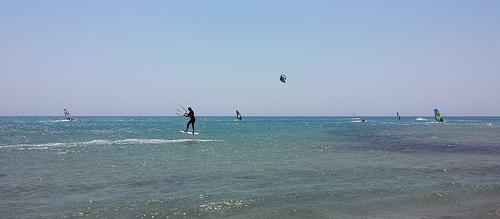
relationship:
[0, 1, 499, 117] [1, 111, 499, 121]
sky has skyline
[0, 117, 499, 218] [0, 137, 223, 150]
water has wave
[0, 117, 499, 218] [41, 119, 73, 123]
water has wave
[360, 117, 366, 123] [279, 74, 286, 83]
person flying kite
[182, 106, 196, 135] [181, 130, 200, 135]
man on top of kiteboard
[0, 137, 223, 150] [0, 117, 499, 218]
wave on top of water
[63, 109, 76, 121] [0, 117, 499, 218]
boat on top of water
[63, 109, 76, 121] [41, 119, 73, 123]
boat making wave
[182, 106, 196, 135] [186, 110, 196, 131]
man wearing wetsuit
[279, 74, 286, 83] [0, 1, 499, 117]
kite in middle of sky